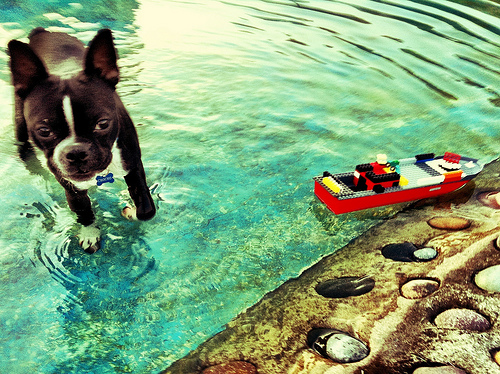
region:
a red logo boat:
[313, 151, 486, 221]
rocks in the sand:
[396, 270, 437, 314]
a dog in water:
[5, 19, 152, 251]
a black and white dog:
[3, 18, 157, 260]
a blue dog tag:
[90, 168, 115, 195]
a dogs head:
[6, 23, 136, 186]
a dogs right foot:
[64, 186, 109, 256]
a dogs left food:
[116, 153, 158, 237]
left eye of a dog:
[90, 113, 113, 138]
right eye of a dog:
[31, 123, 56, 150]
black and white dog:
[0, 22, 170, 205]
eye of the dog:
[85, 105, 126, 140]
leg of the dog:
[115, 165, 172, 230]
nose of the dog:
[62, 135, 92, 170]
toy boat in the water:
[275, 140, 482, 245]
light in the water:
[170, 5, 265, 65]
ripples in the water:
[300, 5, 440, 81]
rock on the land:
[380, 265, 455, 310]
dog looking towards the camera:
[12, 45, 157, 221]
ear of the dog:
[81, 17, 151, 77]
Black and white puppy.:
[3, 19, 157, 254]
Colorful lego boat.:
[310, 146, 488, 218]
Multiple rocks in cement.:
[299, 212, 496, 372]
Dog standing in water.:
[2, 14, 185, 353]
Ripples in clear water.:
[189, 4, 494, 149]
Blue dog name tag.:
[92, 164, 120, 190]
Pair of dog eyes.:
[29, 109, 127, 142]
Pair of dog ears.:
[5, 23, 134, 96]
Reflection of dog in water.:
[45, 179, 189, 361]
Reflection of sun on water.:
[139, 2, 401, 154]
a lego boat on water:
[311, 147, 488, 217]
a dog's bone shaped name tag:
[92, 173, 114, 187]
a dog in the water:
[7, 36, 160, 256]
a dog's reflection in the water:
[40, 201, 150, 368]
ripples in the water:
[211, 2, 495, 126]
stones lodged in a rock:
[300, 212, 497, 369]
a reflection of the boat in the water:
[307, 154, 411, 235]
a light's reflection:
[96, 3, 258, 102]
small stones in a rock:
[388, 200, 493, 371]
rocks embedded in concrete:
[321, 236, 496, 368]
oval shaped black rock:
[309, 270, 381, 300]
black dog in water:
[6, 11, 166, 258]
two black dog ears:
[7, 27, 124, 93]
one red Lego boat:
[302, 124, 484, 214]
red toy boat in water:
[271, 114, 484, 224]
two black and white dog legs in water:
[70, 198, 161, 260]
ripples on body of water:
[203, 8, 493, 120]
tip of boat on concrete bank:
[306, 140, 485, 218]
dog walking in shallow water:
[4, 20, 158, 255]